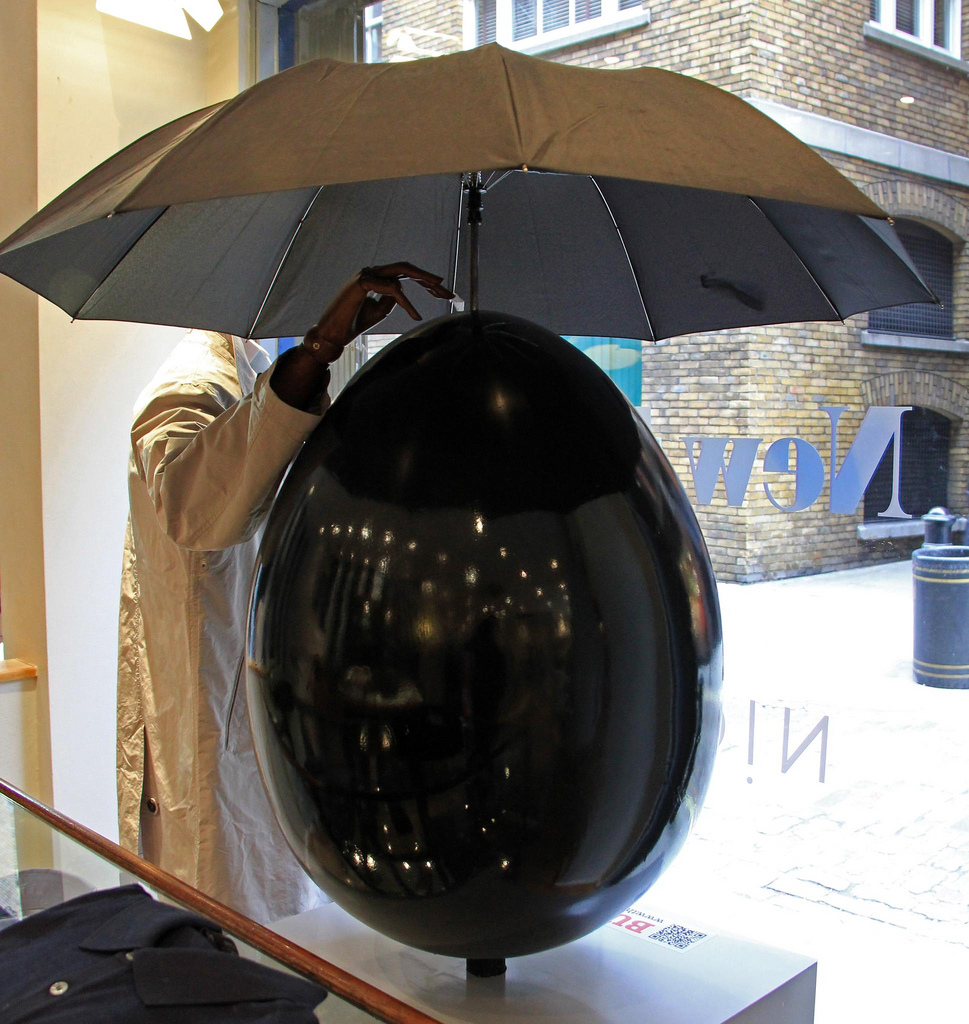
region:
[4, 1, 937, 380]
the umbrella is open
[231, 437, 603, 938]
lights are reflected in the egg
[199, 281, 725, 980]
the egg is black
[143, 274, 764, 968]
the egg is big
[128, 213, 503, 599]
a hand is under the umbrella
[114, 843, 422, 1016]
the railing is made of wood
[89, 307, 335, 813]
the jacket is beige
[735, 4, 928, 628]
the building is across from the window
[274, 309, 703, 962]
Large black balloon on the pole.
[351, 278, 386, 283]
Silver ring on the side of the man's hand.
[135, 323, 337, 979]
White jacket on the man's body.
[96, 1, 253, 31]
White light on the side of the building.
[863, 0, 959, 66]
White frames around the window.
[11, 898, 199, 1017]
Black polo shirt on the table.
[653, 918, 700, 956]
Small GR code on the table.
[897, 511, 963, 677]
Black trash can on the ground.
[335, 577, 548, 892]
reflection on the ball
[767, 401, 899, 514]
writing on the window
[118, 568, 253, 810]
clothing is white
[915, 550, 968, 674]
a trash can outside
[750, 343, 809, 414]
a brick building outside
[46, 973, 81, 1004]
button on the shirt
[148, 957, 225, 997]
collar on the shirt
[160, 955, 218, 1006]
the shirt is blue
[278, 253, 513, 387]
A man's hand touching a black egg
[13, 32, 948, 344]
A hand under a brown umbrella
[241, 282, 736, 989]
A large black egg on display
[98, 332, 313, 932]
A man's overcoat on a mannequin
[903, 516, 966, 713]
A blue trashcan with yellow stripes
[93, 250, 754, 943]
A mannequin next to a large black egg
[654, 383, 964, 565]
Blue letters written on a store window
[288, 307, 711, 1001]
reflections on a black egg display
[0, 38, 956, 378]
an open black umbrella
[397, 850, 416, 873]
small light glare on the sculpture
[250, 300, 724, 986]
large black sculpture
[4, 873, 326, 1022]
a folded black shirt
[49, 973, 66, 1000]
button is on the shirt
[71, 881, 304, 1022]
collar on the top of the shirt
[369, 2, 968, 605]
building is made of brick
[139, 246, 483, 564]
arm is raised in the air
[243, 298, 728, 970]
one black oval-shaped object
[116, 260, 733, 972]
person touching an oval-shaped object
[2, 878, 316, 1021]
one blue button down shirt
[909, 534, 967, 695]
blue garbage can with a yellow stripe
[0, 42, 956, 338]
one large black umbrella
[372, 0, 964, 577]
large brown brick building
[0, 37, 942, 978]
black umbrella over a large egg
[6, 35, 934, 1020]
store window display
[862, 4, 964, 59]
building windows trimmed in white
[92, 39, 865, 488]
an open black umbrella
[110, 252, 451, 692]
a man wearing a coat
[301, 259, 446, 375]
hand underneath umbrella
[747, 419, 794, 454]
brick on the building